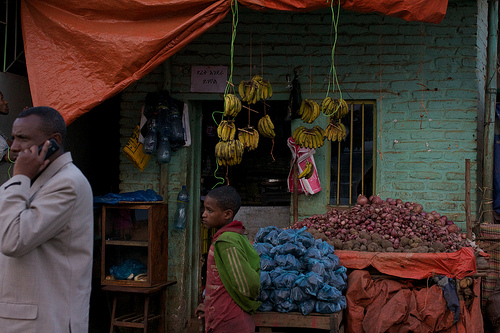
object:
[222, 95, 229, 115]
bananas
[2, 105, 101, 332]
man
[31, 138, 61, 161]
phone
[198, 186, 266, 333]
boy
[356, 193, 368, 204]
onions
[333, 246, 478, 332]
table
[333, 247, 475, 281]
tablecloth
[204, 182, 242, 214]
hair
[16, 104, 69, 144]
hair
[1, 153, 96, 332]
jacket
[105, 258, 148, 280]
bag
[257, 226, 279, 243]
bag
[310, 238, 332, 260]
bag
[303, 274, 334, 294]
bag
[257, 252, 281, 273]
bag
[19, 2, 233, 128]
tarp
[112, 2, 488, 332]
building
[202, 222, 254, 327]
shirt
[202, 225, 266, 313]
jacket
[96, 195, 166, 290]
shelves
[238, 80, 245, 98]
bananas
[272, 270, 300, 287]
bags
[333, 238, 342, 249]
potatoes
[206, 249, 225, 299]
decal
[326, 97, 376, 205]
window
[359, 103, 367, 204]
bars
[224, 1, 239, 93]
ropes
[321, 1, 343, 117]
ropes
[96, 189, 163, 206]
bag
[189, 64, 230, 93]
sign